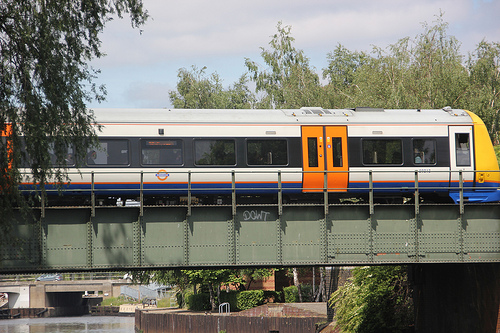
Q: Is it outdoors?
A: Yes, it is outdoors.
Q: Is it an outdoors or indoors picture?
A: It is outdoors.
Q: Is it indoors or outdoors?
A: It is outdoors.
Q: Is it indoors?
A: No, it is outdoors.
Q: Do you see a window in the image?
A: Yes, there is a window.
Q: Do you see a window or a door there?
A: Yes, there is a window.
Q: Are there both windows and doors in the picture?
A: Yes, there are both a window and a door.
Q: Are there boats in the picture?
A: No, there are no boats.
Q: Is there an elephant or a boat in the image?
A: No, there are no boats or elephants.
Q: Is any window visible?
A: Yes, there is a window.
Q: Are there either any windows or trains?
A: Yes, there is a window.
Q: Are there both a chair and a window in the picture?
A: No, there is a window but no chairs.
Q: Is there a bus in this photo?
A: No, there are no buses.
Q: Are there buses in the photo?
A: No, there are no buses.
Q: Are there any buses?
A: No, there are no buses.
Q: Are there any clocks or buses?
A: No, there are no buses or clocks.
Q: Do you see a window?
A: Yes, there is a window.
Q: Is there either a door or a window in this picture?
A: Yes, there is a window.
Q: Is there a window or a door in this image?
A: Yes, there is a window.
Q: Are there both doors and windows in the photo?
A: Yes, there are both a window and a door.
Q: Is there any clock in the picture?
A: No, there are no clocks.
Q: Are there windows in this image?
A: Yes, there is a window.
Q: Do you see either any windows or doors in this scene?
A: Yes, there is a window.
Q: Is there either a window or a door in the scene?
A: Yes, there is a window.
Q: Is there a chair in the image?
A: No, there are no chairs.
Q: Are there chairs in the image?
A: No, there are no chairs.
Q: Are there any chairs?
A: No, there are no chairs.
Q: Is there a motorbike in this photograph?
A: No, there are no motorcycles.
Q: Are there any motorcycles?
A: No, there are no motorcycles.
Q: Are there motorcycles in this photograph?
A: No, there are no motorcycles.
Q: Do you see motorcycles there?
A: No, there are no motorcycles.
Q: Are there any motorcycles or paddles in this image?
A: No, there are no motorcycles or paddles.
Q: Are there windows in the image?
A: Yes, there is a window.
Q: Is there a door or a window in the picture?
A: Yes, there is a window.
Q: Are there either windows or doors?
A: Yes, there is a window.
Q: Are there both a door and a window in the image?
A: Yes, there are both a window and a door.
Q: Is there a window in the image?
A: Yes, there is a window.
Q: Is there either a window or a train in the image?
A: Yes, there is a window.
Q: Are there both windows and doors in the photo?
A: Yes, there are both a window and a door.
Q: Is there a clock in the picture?
A: No, there are no clocks.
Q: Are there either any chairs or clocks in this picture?
A: No, there are no clocks or chairs.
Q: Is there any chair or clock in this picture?
A: No, there are no clocks or chairs.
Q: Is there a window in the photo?
A: Yes, there is a window.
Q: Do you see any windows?
A: Yes, there is a window.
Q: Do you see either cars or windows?
A: Yes, there is a window.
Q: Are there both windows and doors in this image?
A: Yes, there are both a window and a door.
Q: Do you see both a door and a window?
A: Yes, there are both a window and a door.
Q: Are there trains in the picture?
A: Yes, there is a train.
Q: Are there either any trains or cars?
A: Yes, there is a train.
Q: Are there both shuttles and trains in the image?
A: No, there is a train but no shuttles.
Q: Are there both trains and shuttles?
A: No, there is a train but no shuttles.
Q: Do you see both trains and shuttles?
A: No, there is a train but no shuttles.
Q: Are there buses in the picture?
A: No, there are no buses.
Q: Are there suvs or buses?
A: No, there are no buses or suvs.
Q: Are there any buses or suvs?
A: No, there are no buses or suvs.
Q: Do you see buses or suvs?
A: No, there are no buses or suvs.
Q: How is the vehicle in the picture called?
A: The vehicle is a train.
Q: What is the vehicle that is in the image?
A: The vehicle is a train.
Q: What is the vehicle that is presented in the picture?
A: The vehicle is a train.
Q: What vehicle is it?
A: The vehicle is a train.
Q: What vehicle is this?
A: This is a train.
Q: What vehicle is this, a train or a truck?
A: This is a train.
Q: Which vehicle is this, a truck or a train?
A: This is a train.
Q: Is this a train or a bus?
A: This is a train.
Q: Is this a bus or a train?
A: This is a train.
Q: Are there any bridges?
A: Yes, there is a bridge.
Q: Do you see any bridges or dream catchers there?
A: Yes, there is a bridge.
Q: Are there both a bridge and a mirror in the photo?
A: No, there is a bridge but no mirrors.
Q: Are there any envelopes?
A: No, there are no envelopes.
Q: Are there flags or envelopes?
A: No, there are no envelopes or flags.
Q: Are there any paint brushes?
A: No, there are no paint brushes.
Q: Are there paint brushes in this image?
A: No, there are no paint brushes.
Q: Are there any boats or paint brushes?
A: No, there are no paint brushes or boats.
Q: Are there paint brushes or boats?
A: No, there are no paint brushes or boats.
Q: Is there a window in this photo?
A: Yes, there is a window.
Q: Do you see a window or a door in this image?
A: Yes, there is a window.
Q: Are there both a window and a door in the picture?
A: Yes, there are both a window and a door.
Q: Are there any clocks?
A: No, there are no clocks.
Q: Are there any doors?
A: Yes, there are doors.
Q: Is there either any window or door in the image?
A: Yes, there are doors.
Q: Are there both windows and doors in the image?
A: Yes, there are both doors and windows.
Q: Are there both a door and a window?
A: Yes, there are both a door and a window.